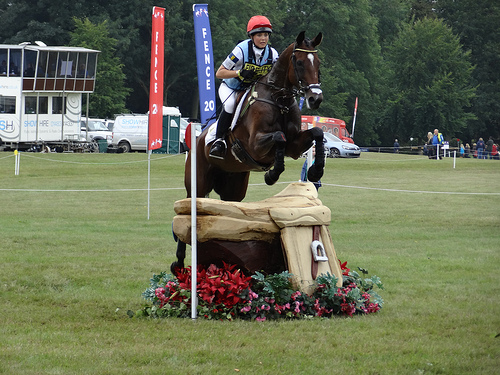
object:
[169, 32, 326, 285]
horse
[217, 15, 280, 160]
woman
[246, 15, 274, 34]
helmet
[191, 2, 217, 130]
sign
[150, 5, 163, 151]
sign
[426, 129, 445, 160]
people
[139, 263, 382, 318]
flowers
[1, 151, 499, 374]
grass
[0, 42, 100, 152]
building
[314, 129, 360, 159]
car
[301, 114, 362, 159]
suv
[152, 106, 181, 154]
potty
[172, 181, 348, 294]
complex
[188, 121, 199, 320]
pole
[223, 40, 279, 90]
vest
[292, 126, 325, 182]
leg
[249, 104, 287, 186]
leg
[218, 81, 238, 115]
pants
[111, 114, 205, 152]
van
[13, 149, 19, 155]
flag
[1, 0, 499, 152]
trees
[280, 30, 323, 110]
head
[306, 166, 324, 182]
hoove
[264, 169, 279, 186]
hoove